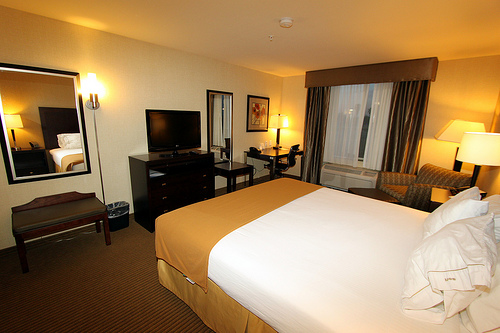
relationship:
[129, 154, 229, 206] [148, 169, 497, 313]
dresser across from bed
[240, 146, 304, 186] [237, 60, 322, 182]
desk in corner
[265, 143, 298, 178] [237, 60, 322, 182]
chair in corner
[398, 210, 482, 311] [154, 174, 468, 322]
pillow on bed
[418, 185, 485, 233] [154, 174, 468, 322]
pillow on bed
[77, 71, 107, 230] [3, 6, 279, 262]
lamp on wall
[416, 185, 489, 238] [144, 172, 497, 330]
pillow on bed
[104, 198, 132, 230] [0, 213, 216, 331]
trash can on floor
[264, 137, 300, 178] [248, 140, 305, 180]
chair at desk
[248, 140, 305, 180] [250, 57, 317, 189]
desk in corner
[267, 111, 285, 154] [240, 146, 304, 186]
lamp on desk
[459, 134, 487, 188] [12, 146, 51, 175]
lamp on table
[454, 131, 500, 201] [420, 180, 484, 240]
lamp on table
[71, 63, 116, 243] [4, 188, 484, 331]
lamp on floor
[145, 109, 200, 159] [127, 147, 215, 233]
tv on dresser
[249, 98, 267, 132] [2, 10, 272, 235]
print on wall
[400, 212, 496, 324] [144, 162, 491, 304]
pillow on bed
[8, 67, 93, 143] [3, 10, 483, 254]
mirror on wall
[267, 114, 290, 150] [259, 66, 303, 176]
lamp in corner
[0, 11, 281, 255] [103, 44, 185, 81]
stool by wall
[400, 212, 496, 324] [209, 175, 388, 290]
pillow on bed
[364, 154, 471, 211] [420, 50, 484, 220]
chair in corner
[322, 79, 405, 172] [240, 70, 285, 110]
window on wall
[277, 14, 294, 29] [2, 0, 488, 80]
smoke detector on ceiling